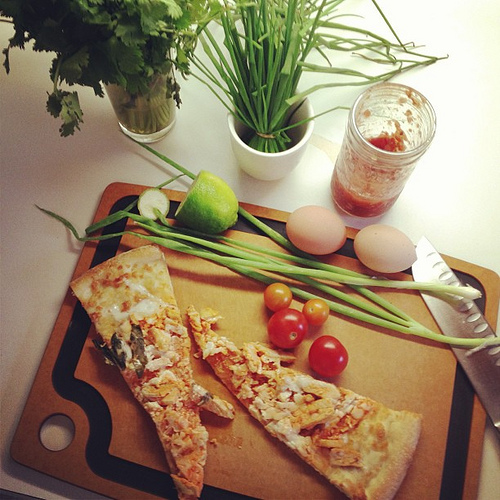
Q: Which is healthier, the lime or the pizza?
A: The lime is healthier than the pizza.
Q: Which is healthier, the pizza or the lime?
A: The lime is healthier than the pizza.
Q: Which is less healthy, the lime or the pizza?
A: The pizza is less healthy than the lime.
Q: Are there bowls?
A: No, there are no bowls.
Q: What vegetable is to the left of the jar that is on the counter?
A: The vegetable is a lime.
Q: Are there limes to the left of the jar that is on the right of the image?
A: Yes, there is a lime to the left of the jar.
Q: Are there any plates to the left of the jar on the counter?
A: No, there is a lime to the left of the jar.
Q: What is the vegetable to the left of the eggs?
A: The vegetable is a lime.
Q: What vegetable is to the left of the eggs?
A: The vegetable is a lime.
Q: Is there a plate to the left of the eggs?
A: No, there is a lime to the left of the eggs.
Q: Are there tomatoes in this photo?
A: Yes, there is a tomato.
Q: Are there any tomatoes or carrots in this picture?
A: Yes, there is a tomato.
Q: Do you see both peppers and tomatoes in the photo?
A: No, there is a tomato but no peppers.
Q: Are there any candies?
A: No, there are no candies.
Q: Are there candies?
A: No, there are no candies.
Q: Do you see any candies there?
A: No, there are no candies.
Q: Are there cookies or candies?
A: No, there are no candies or cookies.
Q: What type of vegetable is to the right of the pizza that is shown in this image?
A: The vegetable is a tomato.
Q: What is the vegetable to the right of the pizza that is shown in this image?
A: The vegetable is a tomato.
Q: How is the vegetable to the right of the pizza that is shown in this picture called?
A: The vegetable is a tomato.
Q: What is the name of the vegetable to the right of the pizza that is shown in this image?
A: The vegetable is a tomato.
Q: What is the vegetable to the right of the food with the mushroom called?
A: The vegetable is a tomato.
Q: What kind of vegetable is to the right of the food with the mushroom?
A: The vegetable is a tomato.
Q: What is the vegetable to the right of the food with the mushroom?
A: The vegetable is a tomato.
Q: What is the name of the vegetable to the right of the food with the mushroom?
A: The vegetable is a tomato.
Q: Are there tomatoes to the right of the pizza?
A: Yes, there is a tomato to the right of the pizza.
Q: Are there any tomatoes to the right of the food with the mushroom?
A: Yes, there is a tomato to the right of the pizza.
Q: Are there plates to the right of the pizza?
A: No, there is a tomato to the right of the pizza.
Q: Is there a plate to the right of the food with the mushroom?
A: No, there is a tomato to the right of the pizza.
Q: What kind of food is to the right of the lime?
A: The food is eggs.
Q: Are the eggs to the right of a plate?
A: No, the eggs are to the right of the lime.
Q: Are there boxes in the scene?
A: No, there are no boxes.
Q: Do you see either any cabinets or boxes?
A: No, there are no boxes or cabinets.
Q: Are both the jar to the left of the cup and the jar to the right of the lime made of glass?
A: Yes, both the jar and the jar are made of glass.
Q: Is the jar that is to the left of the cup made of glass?
A: Yes, the jar is made of glass.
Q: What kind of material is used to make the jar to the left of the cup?
A: The jar is made of glass.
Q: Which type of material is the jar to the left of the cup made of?
A: The jar is made of glass.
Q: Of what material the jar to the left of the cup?
A: The jar is made of glass.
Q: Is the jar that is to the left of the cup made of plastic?
A: No, the jar is made of glass.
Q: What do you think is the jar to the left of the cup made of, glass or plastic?
A: The jar is made of glass.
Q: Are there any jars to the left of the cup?
A: Yes, there is a jar to the left of the cup.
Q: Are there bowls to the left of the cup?
A: No, there is a jar to the left of the cup.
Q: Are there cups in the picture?
A: Yes, there is a cup.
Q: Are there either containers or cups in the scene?
A: Yes, there is a cup.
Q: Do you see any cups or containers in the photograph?
A: Yes, there is a cup.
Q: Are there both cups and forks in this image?
A: No, there is a cup but no forks.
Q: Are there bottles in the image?
A: No, there are no bottles.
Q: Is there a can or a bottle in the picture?
A: No, there are no bottles or cans.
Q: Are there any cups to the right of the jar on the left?
A: Yes, there is a cup to the right of the jar.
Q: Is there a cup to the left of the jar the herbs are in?
A: No, the cup is to the right of the jar.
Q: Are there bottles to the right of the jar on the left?
A: No, there is a cup to the right of the jar.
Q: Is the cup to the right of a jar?
A: Yes, the cup is to the right of a jar.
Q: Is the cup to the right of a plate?
A: No, the cup is to the right of a jar.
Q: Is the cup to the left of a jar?
A: No, the cup is to the right of a jar.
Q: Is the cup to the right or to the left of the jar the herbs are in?
A: The cup is to the right of the jar.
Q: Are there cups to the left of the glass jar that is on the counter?
A: Yes, there is a cup to the left of the jar.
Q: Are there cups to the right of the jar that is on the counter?
A: No, the cup is to the left of the jar.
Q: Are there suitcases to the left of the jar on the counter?
A: No, there is a cup to the left of the jar.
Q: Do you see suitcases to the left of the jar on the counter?
A: No, there is a cup to the left of the jar.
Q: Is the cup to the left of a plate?
A: No, the cup is to the left of a jar.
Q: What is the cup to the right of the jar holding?
A: The cup is holding the herbs.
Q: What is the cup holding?
A: The cup is holding the herbs.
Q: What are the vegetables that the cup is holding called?
A: The vegetables are herbs.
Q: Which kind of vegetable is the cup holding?
A: The cup is holding the herbs.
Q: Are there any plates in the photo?
A: No, there are no plates.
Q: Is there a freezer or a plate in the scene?
A: No, there are no plates or refrigerators.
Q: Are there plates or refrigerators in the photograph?
A: No, there are no plates or refrigerators.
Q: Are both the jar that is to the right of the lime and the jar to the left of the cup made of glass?
A: Yes, both the jar and the jar are made of glass.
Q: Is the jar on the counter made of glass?
A: Yes, the jar is made of glass.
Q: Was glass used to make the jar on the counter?
A: Yes, the jar is made of glass.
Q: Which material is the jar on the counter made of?
A: The jar is made of glass.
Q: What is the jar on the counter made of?
A: The jar is made of glass.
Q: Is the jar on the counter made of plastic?
A: No, the jar is made of glass.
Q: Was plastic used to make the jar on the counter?
A: No, the jar is made of glass.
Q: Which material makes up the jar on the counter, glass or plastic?
A: The jar is made of glass.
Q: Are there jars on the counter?
A: Yes, there is a jar on the counter.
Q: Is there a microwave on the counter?
A: No, there is a jar on the counter.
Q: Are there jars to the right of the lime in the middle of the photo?
A: Yes, there is a jar to the right of the lime.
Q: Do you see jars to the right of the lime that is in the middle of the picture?
A: Yes, there is a jar to the right of the lime.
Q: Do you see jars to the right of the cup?
A: Yes, there is a jar to the right of the cup.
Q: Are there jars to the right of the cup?
A: Yes, there is a jar to the right of the cup.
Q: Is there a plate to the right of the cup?
A: No, there is a jar to the right of the cup.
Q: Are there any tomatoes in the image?
A: Yes, there is a tomato.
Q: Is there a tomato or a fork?
A: Yes, there is a tomato.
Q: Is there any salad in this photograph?
A: No, there is no salad.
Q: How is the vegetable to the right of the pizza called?
A: The vegetable is a tomato.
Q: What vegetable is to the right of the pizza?
A: The vegetable is a tomato.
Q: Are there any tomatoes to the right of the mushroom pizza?
A: Yes, there is a tomato to the right of the pizza.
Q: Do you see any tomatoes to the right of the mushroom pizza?
A: Yes, there is a tomato to the right of the pizza.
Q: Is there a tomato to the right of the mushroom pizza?
A: Yes, there is a tomato to the right of the pizza.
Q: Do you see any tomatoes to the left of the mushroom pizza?
A: No, the tomato is to the right of the pizza.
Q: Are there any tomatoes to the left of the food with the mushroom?
A: No, the tomato is to the right of the pizza.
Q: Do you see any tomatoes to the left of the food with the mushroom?
A: No, the tomato is to the right of the pizza.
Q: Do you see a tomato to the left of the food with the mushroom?
A: No, the tomato is to the right of the pizza.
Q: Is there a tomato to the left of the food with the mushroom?
A: No, the tomato is to the right of the pizza.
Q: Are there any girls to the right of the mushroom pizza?
A: No, there is a tomato to the right of the pizza.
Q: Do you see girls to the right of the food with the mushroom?
A: No, there is a tomato to the right of the pizza.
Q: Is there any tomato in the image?
A: Yes, there are tomatoes.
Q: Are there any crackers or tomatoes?
A: Yes, there are tomatoes.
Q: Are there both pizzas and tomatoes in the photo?
A: Yes, there are both tomatoes and a pizza.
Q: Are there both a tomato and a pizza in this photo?
A: Yes, there are both a tomato and a pizza.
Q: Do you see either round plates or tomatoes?
A: Yes, there are round tomatoes.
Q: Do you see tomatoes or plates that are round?
A: Yes, the tomatoes are round.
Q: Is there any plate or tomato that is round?
A: Yes, the tomatoes are round.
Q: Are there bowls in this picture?
A: No, there are no bowls.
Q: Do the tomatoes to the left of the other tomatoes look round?
A: Yes, the tomatoes are round.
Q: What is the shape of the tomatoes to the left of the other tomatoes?
A: The tomatoes are round.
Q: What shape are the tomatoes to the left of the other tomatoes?
A: The tomatoes are round.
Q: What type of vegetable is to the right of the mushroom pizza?
A: The vegetables are tomatoes.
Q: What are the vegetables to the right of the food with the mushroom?
A: The vegetables are tomatoes.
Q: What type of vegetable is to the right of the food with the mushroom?
A: The vegetables are tomatoes.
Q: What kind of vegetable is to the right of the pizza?
A: The vegetables are tomatoes.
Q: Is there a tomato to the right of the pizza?
A: Yes, there are tomatoes to the right of the pizza.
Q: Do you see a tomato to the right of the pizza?
A: Yes, there are tomatoes to the right of the pizza.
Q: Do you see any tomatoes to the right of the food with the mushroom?
A: Yes, there are tomatoes to the right of the pizza.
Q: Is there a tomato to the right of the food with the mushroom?
A: Yes, there are tomatoes to the right of the pizza.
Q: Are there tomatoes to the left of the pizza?
A: No, the tomatoes are to the right of the pizza.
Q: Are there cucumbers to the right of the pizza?
A: No, there are tomatoes to the right of the pizza.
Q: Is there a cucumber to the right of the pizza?
A: No, there are tomatoes to the right of the pizza.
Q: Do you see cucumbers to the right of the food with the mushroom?
A: No, there are tomatoes to the right of the pizza.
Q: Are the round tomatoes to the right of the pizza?
A: Yes, the tomatoes are to the right of the pizza.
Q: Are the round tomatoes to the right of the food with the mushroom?
A: Yes, the tomatoes are to the right of the pizza.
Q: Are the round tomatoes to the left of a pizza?
A: No, the tomatoes are to the right of a pizza.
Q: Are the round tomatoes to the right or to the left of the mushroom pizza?
A: The tomatoes are to the right of the pizza.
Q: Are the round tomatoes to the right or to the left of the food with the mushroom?
A: The tomatoes are to the right of the pizza.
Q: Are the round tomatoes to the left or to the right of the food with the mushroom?
A: The tomatoes are to the right of the pizza.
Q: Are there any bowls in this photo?
A: No, there are no bowls.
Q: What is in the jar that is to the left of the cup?
A: The herbs are in the jar.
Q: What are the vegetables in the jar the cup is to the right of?
A: The vegetables are herbs.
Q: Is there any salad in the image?
A: No, there is no salad.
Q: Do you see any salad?
A: No, there is no salad.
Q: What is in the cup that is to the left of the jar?
A: The herbs are in the cup.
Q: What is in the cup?
A: The herbs are in the cup.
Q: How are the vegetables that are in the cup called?
A: The vegetables are herbs.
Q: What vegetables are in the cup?
A: The vegetables are herbs.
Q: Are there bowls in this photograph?
A: No, there are no bowls.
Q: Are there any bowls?
A: No, there are no bowls.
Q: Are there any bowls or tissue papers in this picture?
A: No, there are no bowls or tissue papers.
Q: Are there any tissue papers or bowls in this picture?
A: No, there are no bowls or tissue papers.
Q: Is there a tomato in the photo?
A: Yes, there are tomatoes.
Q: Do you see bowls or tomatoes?
A: Yes, there are tomatoes.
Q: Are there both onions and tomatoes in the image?
A: Yes, there are both tomatoes and onions.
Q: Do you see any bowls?
A: No, there are no bowls.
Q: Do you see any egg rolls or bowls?
A: No, there are no bowls or egg rolls.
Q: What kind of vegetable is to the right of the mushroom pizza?
A: The vegetables are tomatoes.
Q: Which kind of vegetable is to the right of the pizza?
A: The vegetables are tomatoes.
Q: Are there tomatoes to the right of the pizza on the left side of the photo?
A: Yes, there are tomatoes to the right of the pizza.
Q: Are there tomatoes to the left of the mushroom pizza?
A: No, the tomatoes are to the right of the pizza.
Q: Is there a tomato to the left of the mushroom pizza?
A: No, the tomatoes are to the right of the pizza.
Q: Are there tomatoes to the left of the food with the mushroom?
A: No, the tomatoes are to the right of the pizza.